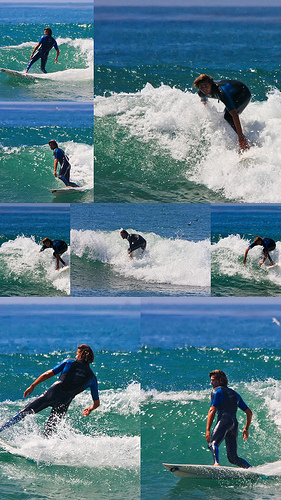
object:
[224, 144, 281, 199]
waves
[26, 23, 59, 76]
person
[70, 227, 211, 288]
wave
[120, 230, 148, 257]
man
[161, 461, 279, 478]
surfboard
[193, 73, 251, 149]
woman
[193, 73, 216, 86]
blond hair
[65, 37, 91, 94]
waves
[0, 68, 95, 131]
ocean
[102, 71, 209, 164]
waves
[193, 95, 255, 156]
surfboard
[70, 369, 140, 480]
waves crashing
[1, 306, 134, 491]
ocean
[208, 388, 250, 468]
shortsleeved wetsuit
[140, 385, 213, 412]
waves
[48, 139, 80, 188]
he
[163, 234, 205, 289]
crashing waves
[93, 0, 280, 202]
water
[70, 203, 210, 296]
ocean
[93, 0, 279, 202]
ocean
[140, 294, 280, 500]
ocean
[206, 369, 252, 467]
he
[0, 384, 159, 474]
wave